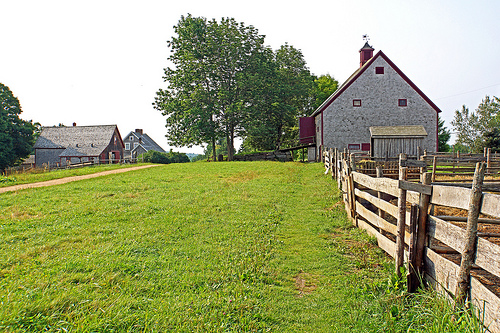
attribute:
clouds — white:
[1, 0, 331, 113]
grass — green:
[181, 165, 304, 315]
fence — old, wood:
[320, 146, 497, 331]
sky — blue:
[2, 2, 499, 154]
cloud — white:
[1, 0, 498, 150]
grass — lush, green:
[0, 159, 333, 331]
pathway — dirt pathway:
[0, 164, 161, 196]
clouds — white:
[340, 13, 484, 71]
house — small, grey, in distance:
[117, 124, 169, 161]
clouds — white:
[43, 41, 98, 82]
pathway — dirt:
[0, 163, 165, 190]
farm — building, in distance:
[24, 114, 179, 171]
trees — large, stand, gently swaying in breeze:
[148, 15, 347, 170]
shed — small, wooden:
[359, 117, 439, 169]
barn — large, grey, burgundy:
[310, 42, 442, 162]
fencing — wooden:
[315, 139, 492, 302]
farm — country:
[201, 32, 499, 215]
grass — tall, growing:
[404, 275, 461, 330]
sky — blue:
[410, 0, 498, 144]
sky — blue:
[0, 11, 479, 150]